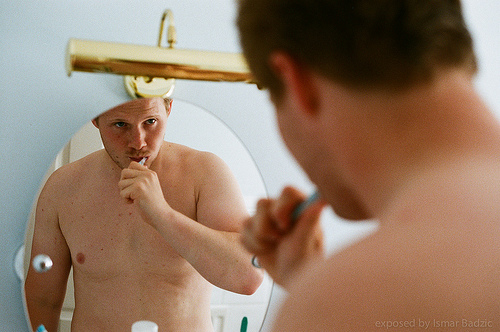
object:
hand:
[118, 159, 170, 215]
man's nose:
[127, 125, 152, 152]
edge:
[228, 129, 254, 157]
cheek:
[273, 103, 357, 210]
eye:
[108, 118, 130, 131]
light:
[66, 38, 264, 91]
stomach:
[88, 264, 179, 323]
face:
[99, 97, 168, 172]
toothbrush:
[250, 185, 328, 272]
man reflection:
[22, 96, 262, 331]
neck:
[360, 103, 500, 227]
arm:
[165, 156, 270, 292]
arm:
[21, 182, 72, 325]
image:
[23, 97, 264, 331]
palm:
[246, 229, 302, 267]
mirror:
[21, 94, 278, 331]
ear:
[269, 50, 322, 124]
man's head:
[231, 0, 499, 220]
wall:
[0, 1, 500, 330]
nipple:
[72, 248, 89, 268]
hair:
[235, 0, 484, 98]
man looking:
[235, 0, 500, 331]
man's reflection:
[14, 97, 268, 331]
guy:
[236, 0, 500, 331]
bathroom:
[0, 0, 500, 331]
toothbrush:
[132, 155, 151, 173]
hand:
[235, 182, 328, 295]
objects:
[28, 316, 264, 331]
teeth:
[125, 155, 142, 164]